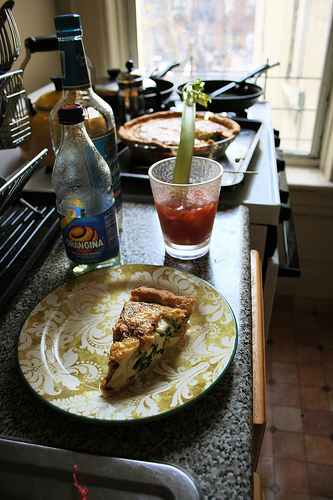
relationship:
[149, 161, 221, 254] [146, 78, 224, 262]
glass with bloody mary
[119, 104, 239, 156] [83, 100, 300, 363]
pie on oven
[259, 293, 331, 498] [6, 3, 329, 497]
flooring in kitchen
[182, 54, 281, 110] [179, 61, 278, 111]
black frying pan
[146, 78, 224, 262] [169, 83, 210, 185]
bloody mary with celery stick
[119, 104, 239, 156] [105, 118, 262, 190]
pie on cookie sheet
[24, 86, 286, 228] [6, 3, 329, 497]
stove in kitchen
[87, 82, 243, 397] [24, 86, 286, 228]
food on stove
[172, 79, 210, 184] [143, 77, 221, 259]
celery stalk in cocktail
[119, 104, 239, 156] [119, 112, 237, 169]
pie in tray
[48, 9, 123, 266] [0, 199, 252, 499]
bottles on counter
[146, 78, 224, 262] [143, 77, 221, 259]
bloody mary mary cocktail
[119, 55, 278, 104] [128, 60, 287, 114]
nonstick frying pans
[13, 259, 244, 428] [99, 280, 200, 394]
plate has pie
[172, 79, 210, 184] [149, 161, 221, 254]
celery stalk in glass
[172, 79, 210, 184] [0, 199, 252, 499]
celery stalk on counter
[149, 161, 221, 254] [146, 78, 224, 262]
glass has bloody mary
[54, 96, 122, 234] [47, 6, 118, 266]
alcohol on bottle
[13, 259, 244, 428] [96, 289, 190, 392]
plate of pie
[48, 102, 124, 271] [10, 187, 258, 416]
bottles on countertop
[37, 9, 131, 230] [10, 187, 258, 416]
bottles on countertop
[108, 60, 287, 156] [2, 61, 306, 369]
pans on stove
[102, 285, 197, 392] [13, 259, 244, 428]
pie on plate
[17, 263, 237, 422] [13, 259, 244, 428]
design on plate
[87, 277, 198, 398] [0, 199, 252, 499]
food on counter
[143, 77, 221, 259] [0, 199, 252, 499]
cocktail on counter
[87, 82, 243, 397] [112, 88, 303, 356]
food on stove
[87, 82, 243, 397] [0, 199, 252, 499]
food on counter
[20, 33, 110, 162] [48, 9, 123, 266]
kettle behind bottles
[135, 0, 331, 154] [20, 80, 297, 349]
window next to stove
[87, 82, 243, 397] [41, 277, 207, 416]
food on plate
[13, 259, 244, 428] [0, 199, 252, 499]
plate on counter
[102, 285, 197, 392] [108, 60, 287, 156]
pie in pans